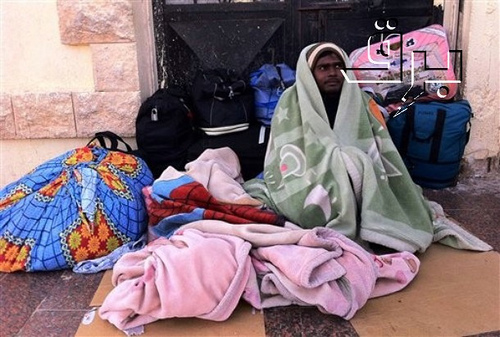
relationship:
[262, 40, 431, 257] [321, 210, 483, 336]
man on cardboard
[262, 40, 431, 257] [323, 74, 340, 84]
man with mustache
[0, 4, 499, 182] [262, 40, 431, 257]
building behind man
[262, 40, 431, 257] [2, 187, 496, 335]
man on sidewalk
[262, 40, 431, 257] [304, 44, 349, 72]
man wearing cap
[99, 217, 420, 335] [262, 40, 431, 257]
blanket in front of man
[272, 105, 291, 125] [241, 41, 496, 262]
star on blanket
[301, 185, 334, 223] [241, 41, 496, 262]
moon on blanket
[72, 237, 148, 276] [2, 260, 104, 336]
clothes on floor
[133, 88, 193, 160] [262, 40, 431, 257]
bag behind man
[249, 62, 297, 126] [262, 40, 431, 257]
bag behind man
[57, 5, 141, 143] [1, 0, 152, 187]
stones on wall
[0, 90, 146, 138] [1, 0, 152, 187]
bricks on wall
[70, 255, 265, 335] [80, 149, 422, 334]
cardboard under sheet